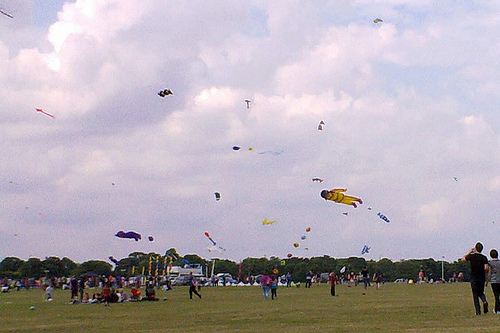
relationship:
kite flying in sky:
[318, 187, 364, 209] [0, 0, 500, 264]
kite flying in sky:
[31, 104, 56, 120] [0, 0, 500, 264]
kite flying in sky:
[156, 84, 173, 97] [0, 0, 500, 264]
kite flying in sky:
[113, 228, 141, 242] [0, 0, 500, 264]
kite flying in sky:
[357, 243, 374, 253] [0, 0, 500, 264]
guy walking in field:
[460, 241, 491, 315] [0, 280, 500, 330]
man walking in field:
[325, 267, 343, 297] [0, 280, 500, 330]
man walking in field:
[181, 268, 201, 299] [0, 280, 500, 330]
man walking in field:
[64, 268, 80, 302] [0, 280, 500, 330]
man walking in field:
[75, 273, 90, 302] [0, 280, 500, 330]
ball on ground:
[26, 302, 36, 312] [0, 281, 499, 329]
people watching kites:
[0, 264, 500, 316] [31, 76, 461, 265]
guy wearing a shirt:
[460, 241, 491, 315] [464, 254, 487, 288]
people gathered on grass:
[59, 276, 159, 303] [62, 305, 173, 329]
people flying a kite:
[62, 267, 170, 318] [103, 212, 163, 250]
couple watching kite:
[459, 238, 496, 272] [318, 187, 364, 209]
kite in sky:
[318, 187, 364, 209] [216, 109, 461, 302]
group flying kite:
[62, 264, 172, 303] [113, 228, 141, 242]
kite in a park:
[113, 228, 141, 242] [2, 212, 489, 330]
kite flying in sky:
[34, 106, 57, 120] [9, 30, 186, 229]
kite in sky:
[318, 187, 364, 209] [110, 66, 423, 286]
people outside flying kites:
[259, 269, 273, 300] [173, 126, 402, 291]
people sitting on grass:
[259, 269, 273, 300] [55, 292, 206, 327]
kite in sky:
[312, 183, 374, 210] [210, 120, 411, 260]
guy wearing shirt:
[463, 235, 496, 267] [459, 251, 494, 280]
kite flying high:
[34, 106, 57, 120] [17, 57, 426, 278]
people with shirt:
[259, 269, 273, 300] [257, 272, 292, 294]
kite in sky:
[253, 215, 275, 229] [116, 93, 452, 253]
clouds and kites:
[0, 0, 499, 263] [233, 159, 398, 273]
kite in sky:
[318, 187, 364, 209] [230, 110, 480, 287]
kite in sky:
[107, 223, 170, 253] [23, 114, 297, 310]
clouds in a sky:
[93, 38, 460, 205] [23, 30, 498, 303]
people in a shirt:
[259, 269, 273, 300] [260, 272, 281, 293]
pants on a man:
[182, 289, 203, 299] [187, 271, 202, 301]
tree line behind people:
[0, 200, 497, 280] [57, 266, 498, 311]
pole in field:
[436, 214, 447, 285] [264, 194, 495, 333]